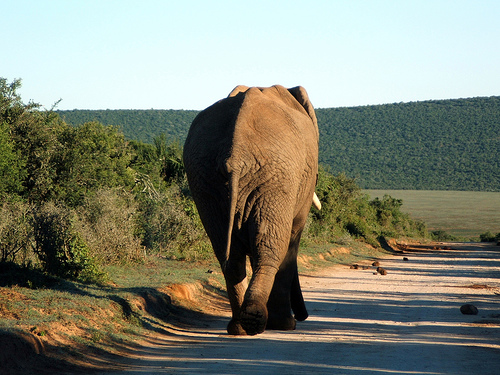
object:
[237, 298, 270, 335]
foot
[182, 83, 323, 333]
elephant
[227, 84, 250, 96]
ear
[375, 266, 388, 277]
rocks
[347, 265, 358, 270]
rocks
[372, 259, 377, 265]
rocks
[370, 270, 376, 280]
rocks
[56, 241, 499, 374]
ground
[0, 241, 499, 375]
path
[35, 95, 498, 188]
hill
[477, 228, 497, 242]
shrubs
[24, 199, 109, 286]
shrubs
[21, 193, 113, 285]
shrubs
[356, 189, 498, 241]
field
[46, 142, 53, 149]
leaves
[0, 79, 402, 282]
forest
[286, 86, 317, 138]
ear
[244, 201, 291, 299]
leg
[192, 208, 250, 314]
leg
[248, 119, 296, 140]
skin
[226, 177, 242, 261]
tail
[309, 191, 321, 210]
tusk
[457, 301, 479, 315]
dung